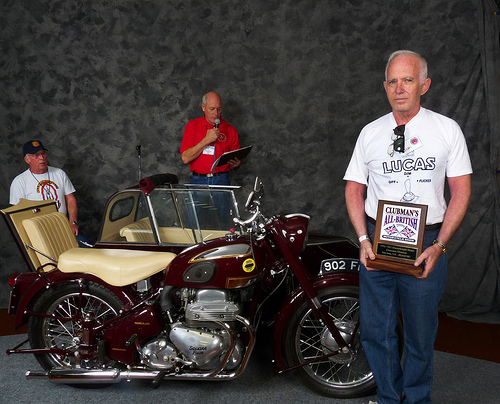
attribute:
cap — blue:
[24, 141, 44, 155]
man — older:
[7, 134, 77, 246]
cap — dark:
[22, 138, 47, 160]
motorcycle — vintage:
[9, 197, 386, 389]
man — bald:
[167, 82, 270, 218]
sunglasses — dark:
[390, 118, 406, 158]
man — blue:
[6, 137, 93, 245]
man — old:
[179, 89, 254, 229]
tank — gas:
[178, 235, 275, 299]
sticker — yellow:
[235, 258, 259, 270]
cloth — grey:
[0, 0, 496, 327]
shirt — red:
[179, 114, 239, 173]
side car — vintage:
[100, 143, 247, 253]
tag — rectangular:
[200, 140, 216, 156]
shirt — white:
[337, 110, 473, 227]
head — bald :
[198, 94, 225, 121]